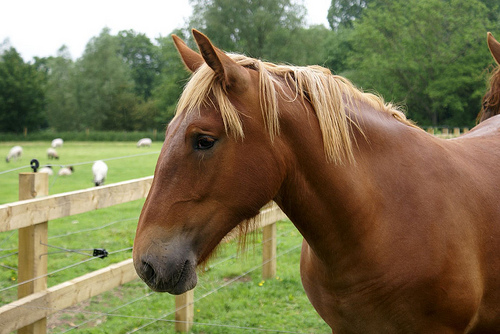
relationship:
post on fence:
[16, 170, 48, 332] [1, 169, 286, 331]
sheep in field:
[127, 130, 154, 152] [0, 136, 339, 330]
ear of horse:
[165, 31, 202, 79] [125, 22, 497, 329]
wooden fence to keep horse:
[2, 169, 289, 331] [125, 22, 497, 329]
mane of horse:
[164, 44, 432, 181] [125, 22, 497, 329]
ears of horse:
[168, 23, 250, 89] [125, 22, 497, 329]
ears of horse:
[168, 23, 250, 89] [473, 28, 499, 122]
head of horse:
[125, 19, 315, 300] [105, 15, 499, 315]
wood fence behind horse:
[6, 174, 133, 325] [125, 22, 497, 329]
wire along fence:
[5, 243, 130, 293] [1, 169, 286, 331]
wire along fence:
[99, 275, 319, 325] [1, 169, 286, 331]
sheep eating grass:
[89, 158, 110, 182] [120, 150, 142, 172]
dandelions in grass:
[258, 276, 267, 288] [1, 141, 331, 331]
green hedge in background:
[6, 127, 158, 147] [6, 4, 476, 143]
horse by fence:
[125, 22, 497, 329] [1, 169, 286, 331]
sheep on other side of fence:
[39, 127, 121, 183] [3, 149, 289, 332]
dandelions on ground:
[258, 279, 266, 286] [4, 140, 323, 331]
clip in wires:
[88, 240, 110, 262] [3, 148, 305, 332]